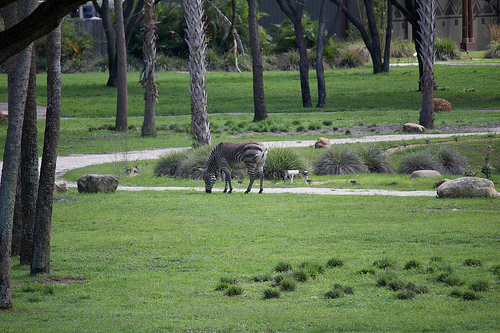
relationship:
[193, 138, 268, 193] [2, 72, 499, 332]
zebra in field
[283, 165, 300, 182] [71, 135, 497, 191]
object on grass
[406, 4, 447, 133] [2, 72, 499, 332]
tree in field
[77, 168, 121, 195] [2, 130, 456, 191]
rock near road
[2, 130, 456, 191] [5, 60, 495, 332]
road in park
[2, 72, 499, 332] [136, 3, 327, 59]
field of plants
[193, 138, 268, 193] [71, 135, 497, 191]
zebra on grass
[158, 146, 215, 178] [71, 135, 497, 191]
bush out of grass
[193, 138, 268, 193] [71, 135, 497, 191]
zebra eating grass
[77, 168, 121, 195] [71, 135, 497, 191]
rock on grass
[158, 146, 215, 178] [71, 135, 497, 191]
bush on top of grass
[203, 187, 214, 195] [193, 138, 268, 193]
mouth of zebra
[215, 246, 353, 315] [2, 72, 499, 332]
crab grass in field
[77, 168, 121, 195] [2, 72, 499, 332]
rock in field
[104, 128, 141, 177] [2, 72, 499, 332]
flowers in field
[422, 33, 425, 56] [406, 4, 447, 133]
leaves of tree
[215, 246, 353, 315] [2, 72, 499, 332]
crab grass on field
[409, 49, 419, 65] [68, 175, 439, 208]
light near path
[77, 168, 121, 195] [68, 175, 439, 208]
rock by path